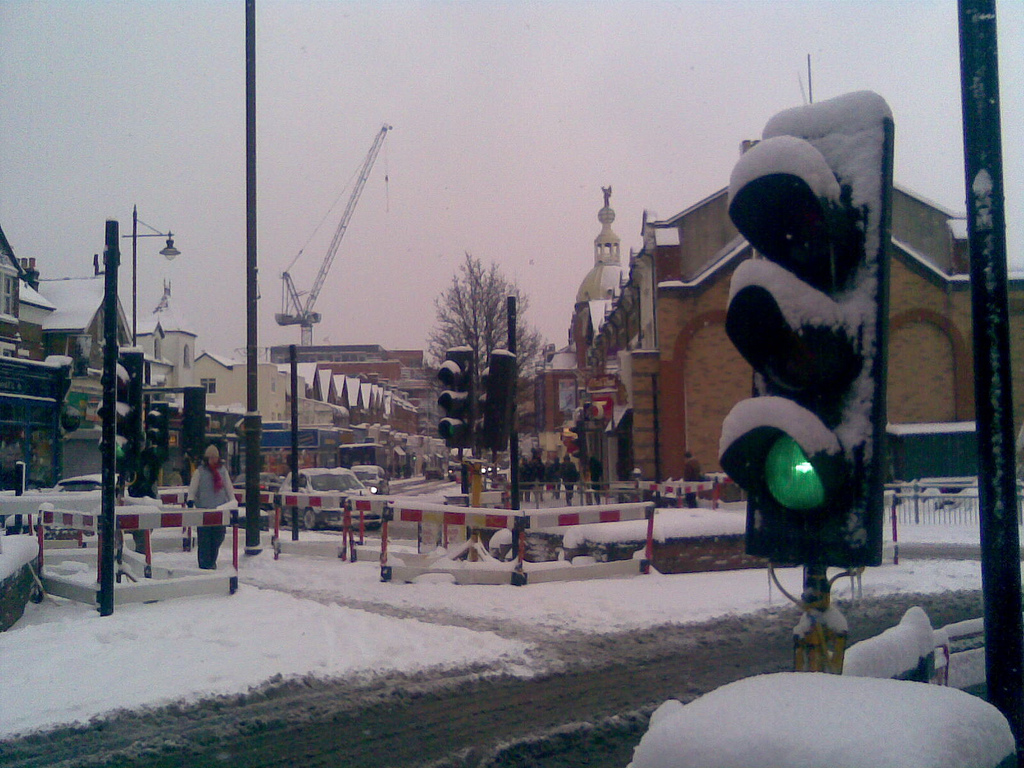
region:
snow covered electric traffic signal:
[719, 86, 893, 561]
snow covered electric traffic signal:
[435, 348, 471, 451]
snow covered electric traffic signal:
[476, 349, 514, 451]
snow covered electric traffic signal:
[100, 348, 145, 465]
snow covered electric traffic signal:
[146, 402, 167, 463]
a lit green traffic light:
[763, 439, 822, 507]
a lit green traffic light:
[113, 439, 121, 460]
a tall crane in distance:
[273, 121, 401, 347]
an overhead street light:
[156, 232, 180, 261]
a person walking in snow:
[188, 444, 243, 569]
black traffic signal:
[723, 104, 910, 557]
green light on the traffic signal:
[734, 444, 833, 517]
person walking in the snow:
[183, 453, 244, 565]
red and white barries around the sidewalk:
[3, 471, 692, 611]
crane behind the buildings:
[274, 109, 398, 351]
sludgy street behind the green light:
[15, 580, 1022, 762]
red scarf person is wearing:
[204, 457, 227, 487]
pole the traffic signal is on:
[779, 569, 849, 671]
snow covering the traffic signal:
[732, 96, 878, 473]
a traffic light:
[705, 80, 906, 669]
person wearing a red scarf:
[180, 440, 245, 580]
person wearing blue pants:
[180, 438, 238, 581]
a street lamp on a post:
[117, 188, 191, 350]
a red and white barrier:
[103, 495, 252, 594]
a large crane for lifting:
[269, 109, 400, 347]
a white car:
[273, 460, 385, 528]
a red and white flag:
[576, 380, 619, 437]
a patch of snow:
[618, 658, 1021, 763]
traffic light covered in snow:
[719, 92, 900, 680]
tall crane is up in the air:
[275, 121, 394, 338]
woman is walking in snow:
[185, 440, 239, 571]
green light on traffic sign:
[755, 432, 833, 521]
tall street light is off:
[123, 195, 181, 347]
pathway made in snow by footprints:
[240, 574, 589, 673]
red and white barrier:
[375, 499, 661, 589]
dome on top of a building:
[574, 180, 636, 304]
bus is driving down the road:
[333, 439, 391, 497]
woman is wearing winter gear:
[180, 439, 242, 569]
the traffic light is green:
[630, 35, 902, 628]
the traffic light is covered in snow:
[653, 1, 919, 577]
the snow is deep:
[166, 610, 525, 757]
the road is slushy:
[339, 612, 660, 755]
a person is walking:
[143, 419, 271, 575]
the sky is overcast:
[203, 2, 685, 326]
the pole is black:
[39, 143, 167, 633]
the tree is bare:
[378, 210, 553, 410]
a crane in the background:
[256, 81, 440, 342]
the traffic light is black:
[681, 61, 903, 589]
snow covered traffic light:
[711, 89, 899, 571]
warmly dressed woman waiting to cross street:
[177, 428, 245, 583]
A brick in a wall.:
[695, 368, 714, 381]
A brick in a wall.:
[713, 380, 730, 388]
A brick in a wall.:
[915, 377, 925, 387]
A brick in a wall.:
[919, 351, 924, 356]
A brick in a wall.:
[912, 332, 926, 339]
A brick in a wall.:
[897, 285, 910, 295]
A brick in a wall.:
[926, 370, 946, 378]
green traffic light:
[751, 398, 841, 532]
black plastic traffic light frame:
[712, 76, 890, 564]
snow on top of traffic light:
[721, 82, 898, 566]